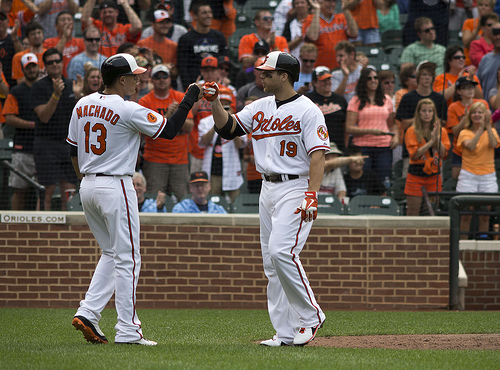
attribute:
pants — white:
[71, 170, 143, 341]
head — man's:
[103, 66, 135, 93]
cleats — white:
[260, 313, 326, 345]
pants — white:
[76, 171, 146, 343]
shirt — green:
[397, 42, 446, 64]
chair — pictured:
[343, 194, 415, 221]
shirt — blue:
[171, 197, 226, 213]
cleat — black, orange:
[64, 317, 116, 347]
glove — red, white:
[299, 184, 318, 229]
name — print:
[248, 109, 300, 132]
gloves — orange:
[198, 80, 320, 222]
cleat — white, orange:
[294, 300, 324, 350]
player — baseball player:
[56, 54, 208, 352]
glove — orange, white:
[294, 190, 319, 220]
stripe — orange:
[113, 179, 146, 331]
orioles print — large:
[245, 110, 304, 141]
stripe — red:
[119, 176, 147, 335]